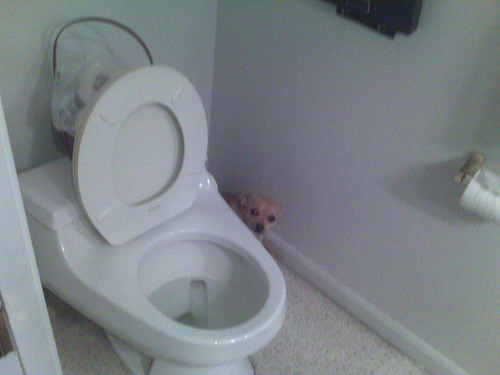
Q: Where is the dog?
A: In the corner.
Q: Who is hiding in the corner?
A: A dog.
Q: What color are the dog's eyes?
A: Black.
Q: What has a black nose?
A: The dog.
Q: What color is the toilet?
A: White.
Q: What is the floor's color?
A: White.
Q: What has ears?
A: The dog.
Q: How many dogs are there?
A: 1.